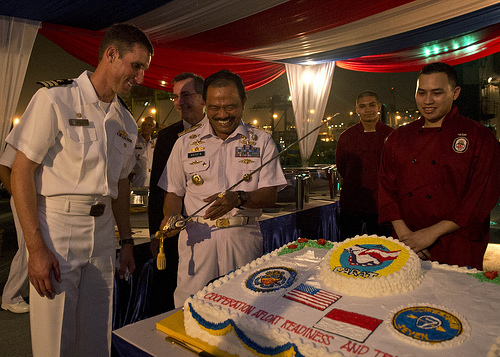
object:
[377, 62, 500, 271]
chef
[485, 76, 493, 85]
light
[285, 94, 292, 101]
light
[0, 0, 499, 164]
background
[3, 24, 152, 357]
captain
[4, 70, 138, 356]
dress whites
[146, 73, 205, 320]
man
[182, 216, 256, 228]
belt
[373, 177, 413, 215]
ground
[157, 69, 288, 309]
man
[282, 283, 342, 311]
flag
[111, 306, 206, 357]
table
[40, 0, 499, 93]
fabric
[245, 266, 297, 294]
navy logo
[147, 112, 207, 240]
suit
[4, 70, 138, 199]
shirt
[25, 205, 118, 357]
pants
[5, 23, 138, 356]
man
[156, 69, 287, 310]
captain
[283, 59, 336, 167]
curtain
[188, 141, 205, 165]
badges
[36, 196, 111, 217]
belt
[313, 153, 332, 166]
green leaves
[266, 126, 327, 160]
floor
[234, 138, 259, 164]
awards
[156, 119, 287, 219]
shirt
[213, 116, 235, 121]
mustache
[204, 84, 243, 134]
face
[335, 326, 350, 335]
white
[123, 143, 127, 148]
button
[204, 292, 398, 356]
indonesia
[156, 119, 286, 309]
indonesian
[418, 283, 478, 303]
white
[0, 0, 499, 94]
ceiling